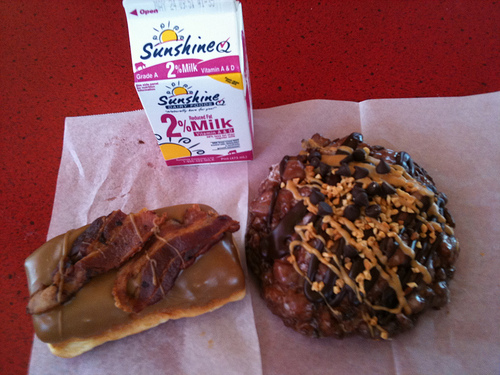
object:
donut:
[249, 132, 458, 339]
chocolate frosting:
[250, 180, 293, 233]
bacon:
[113, 206, 237, 312]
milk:
[123, 0, 251, 166]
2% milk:
[166, 62, 198, 78]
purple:
[214, 55, 238, 67]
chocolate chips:
[345, 132, 364, 146]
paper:
[29, 89, 499, 375]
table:
[0, 0, 499, 375]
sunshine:
[140, 34, 215, 59]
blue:
[140, 43, 152, 60]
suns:
[153, 21, 184, 45]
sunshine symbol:
[154, 133, 205, 160]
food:
[26, 203, 245, 356]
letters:
[158, 96, 167, 105]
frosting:
[321, 155, 349, 167]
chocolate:
[267, 200, 306, 257]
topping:
[343, 204, 359, 219]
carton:
[135, 62, 145, 70]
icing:
[396, 151, 415, 176]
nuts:
[327, 185, 343, 196]